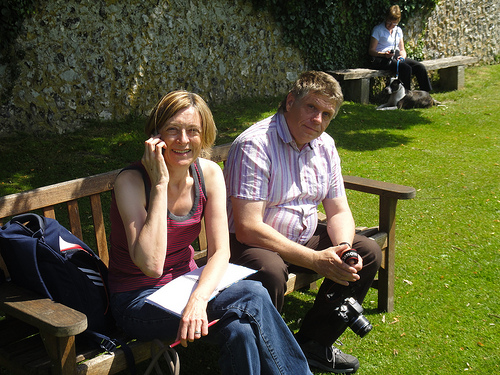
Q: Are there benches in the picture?
A: Yes, there is a bench.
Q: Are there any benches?
A: Yes, there is a bench.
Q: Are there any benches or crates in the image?
A: Yes, there is a bench.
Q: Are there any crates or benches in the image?
A: Yes, there is a bench.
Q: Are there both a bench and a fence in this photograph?
A: No, there is a bench but no fences.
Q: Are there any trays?
A: No, there are no trays.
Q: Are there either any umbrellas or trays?
A: No, there are no trays or umbrellas.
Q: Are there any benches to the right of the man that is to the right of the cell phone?
A: Yes, there is a bench to the right of the man.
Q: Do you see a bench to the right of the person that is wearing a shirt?
A: Yes, there is a bench to the right of the man.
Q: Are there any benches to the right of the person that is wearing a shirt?
A: Yes, there is a bench to the right of the man.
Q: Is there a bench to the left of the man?
A: No, the bench is to the right of the man.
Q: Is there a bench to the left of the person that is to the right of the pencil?
A: No, the bench is to the right of the man.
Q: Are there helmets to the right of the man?
A: No, there is a bench to the right of the man.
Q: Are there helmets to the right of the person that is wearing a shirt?
A: No, there is a bench to the right of the man.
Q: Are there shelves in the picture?
A: No, there are no shelves.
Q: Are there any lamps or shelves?
A: No, there are no shelves or lamps.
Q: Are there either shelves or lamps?
A: No, there are no shelves or lamps.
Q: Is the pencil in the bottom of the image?
A: Yes, the pencil is in the bottom of the image.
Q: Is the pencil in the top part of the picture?
A: No, the pencil is in the bottom of the image.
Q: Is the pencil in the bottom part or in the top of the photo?
A: The pencil is in the bottom of the image.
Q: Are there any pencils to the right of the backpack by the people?
A: Yes, there is a pencil to the right of the backpack.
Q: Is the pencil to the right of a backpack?
A: Yes, the pencil is to the right of a backpack.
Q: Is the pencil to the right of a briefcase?
A: No, the pencil is to the right of a backpack.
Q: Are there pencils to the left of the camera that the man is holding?
A: Yes, there is a pencil to the left of the camera.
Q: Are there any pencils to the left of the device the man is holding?
A: Yes, there is a pencil to the left of the camera.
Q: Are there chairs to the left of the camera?
A: No, there is a pencil to the left of the camera.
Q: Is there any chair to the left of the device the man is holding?
A: No, there is a pencil to the left of the camera.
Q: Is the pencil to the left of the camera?
A: Yes, the pencil is to the left of the camera.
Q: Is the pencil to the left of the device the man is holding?
A: Yes, the pencil is to the left of the camera.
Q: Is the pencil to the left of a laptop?
A: No, the pencil is to the left of the camera.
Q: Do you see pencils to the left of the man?
A: Yes, there is a pencil to the left of the man.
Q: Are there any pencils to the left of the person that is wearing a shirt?
A: Yes, there is a pencil to the left of the man.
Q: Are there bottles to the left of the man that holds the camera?
A: No, there is a pencil to the left of the man.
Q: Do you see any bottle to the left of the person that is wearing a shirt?
A: No, there is a pencil to the left of the man.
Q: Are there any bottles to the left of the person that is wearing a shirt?
A: No, there is a pencil to the left of the man.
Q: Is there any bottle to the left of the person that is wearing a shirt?
A: No, there is a pencil to the left of the man.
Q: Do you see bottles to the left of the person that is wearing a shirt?
A: No, there is a pencil to the left of the man.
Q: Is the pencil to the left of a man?
A: Yes, the pencil is to the left of a man.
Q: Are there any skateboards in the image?
A: No, there are no skateboards.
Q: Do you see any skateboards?
A: No, there are no skateboards.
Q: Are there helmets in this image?
A: No, there are no helmets.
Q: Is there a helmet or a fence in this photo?
A: No, there are no helmets or fences.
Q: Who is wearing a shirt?
A: The man is wearing a shirt.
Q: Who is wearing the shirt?
A: The man is wearing a shirt.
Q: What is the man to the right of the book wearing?
A: The man is wearing a shirt.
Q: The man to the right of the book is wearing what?
A: The man is wearing a shirt.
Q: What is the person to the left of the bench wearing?
A: The man is wearing a shirt.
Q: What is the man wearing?
A: The man is wearing a shirt.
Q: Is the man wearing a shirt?
A: Yes, the man is wearing a shirt.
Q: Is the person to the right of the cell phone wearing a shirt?
A: Yes, the man is wearing a shirt.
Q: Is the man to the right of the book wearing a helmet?
A: No, the man is wearing a shirt.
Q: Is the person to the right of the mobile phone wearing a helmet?
A: No, the man is wearing a shirt.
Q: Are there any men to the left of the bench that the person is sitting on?
A: Yes, there is a man to the left of the bench.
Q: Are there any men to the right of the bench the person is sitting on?
A: No, the man is to the left of the bench.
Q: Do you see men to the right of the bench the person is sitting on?
A: No, the man is to the left of the bench.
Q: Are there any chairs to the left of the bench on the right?
A: No, there is a man to the left of the bench.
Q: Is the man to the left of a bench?
A: Yes, the man is to the left of a bench.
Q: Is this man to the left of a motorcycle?
A: No, the man is to the left of a bench.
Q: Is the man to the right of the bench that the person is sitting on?
A: No, the man is to the left of the bench.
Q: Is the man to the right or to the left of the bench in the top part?
A: The man is to the left of the bench.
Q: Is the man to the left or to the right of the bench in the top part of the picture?
A: The man is to the left of the bench.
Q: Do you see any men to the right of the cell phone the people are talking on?
A: Yes, there is a man to the right of the mobile phone.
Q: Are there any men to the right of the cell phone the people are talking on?
A: Yes, there is a man to the right of the mobile phone.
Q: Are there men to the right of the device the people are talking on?
A: Yes, there is a man to the right of the mobile phone.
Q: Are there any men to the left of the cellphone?
A: No, the man is to the right of the cellphone.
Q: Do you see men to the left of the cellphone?
A: No, the man is to the right of the cellphone.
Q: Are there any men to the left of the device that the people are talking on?
A: No, the man is to the right of the cellphone.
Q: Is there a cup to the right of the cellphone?
A: No, there is a man to the right of the cellphone.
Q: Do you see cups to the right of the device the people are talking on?
A: No, there is a man to the right of the cellphone.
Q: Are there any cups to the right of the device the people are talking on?
A: No, there is a man to the right of the cellphone.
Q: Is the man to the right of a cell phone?
A: Yes, the man is to the right of a cell phone.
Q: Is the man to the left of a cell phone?
A: No, the man is to the right of a cell phone.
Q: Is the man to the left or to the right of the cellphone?
A: The man is to the right of the cellphone.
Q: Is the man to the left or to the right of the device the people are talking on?
A: The man is to the right of the cellphone.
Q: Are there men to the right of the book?
A: Yes, there is a man to the right of the book.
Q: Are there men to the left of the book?
A: No, the man is to the right of the book.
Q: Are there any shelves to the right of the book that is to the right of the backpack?
A: No, there is a man to the right of the book.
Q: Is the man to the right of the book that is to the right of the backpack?
A: Yes, the man is to the right of the book.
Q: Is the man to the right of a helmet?
A: No, the man is to the right of the book.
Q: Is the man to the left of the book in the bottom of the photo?
A: No, the man is to the right of the book.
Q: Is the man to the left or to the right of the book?
A: The man is to the right of the book.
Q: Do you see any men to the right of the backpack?
A: Yes, there is a man to the right of the backpack.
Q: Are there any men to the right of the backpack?
A: Yes, there is a man to the right of the backpack.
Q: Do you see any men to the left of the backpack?
A: No, the man is to the right of the backpack.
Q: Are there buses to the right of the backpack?
A: No, there is a man to the right of the backpack.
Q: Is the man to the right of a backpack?
A: Yes, the man is to the right of a backpack.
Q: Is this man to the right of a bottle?
A: No, the man is to the right of a backpack.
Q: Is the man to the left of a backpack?
A: No, the man is to the right of a backpack.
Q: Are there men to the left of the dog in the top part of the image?
A: Yes, there is a man to the left of the dog.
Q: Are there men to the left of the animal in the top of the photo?
A: Yes, there is a man to the left of the dog.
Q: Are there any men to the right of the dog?
A: No, the man is to the left of the dog.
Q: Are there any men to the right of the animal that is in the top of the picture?
A: No, the man is to the left of the dog.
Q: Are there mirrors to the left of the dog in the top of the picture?
A: No, there is a man to the left of the dog.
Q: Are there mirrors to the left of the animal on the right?
A: No, there is a man to the left of the dog.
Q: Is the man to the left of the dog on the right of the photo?
A: Yes, the man is to the left of the dog.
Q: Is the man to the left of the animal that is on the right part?
A: Yes, the man is to the left of the dog.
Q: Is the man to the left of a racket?
A: No, the man is to the left of the dog.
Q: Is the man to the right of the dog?
A: No, the man is to the left of the dog.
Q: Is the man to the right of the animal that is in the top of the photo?
A: No, the man is to the left of the dog.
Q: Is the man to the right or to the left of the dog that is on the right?
A: The man is to the left of the dog.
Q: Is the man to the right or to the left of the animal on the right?
A: The man is to the left of the dog.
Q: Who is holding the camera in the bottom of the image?
A: The man is holding the camera.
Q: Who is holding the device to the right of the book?
A: The man is holding the camera.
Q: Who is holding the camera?
A: The man is holding the camera.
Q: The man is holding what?
A: The man is holding the camera.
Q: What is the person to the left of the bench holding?
A: The man is holding the camera.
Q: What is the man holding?
A: The man is holding the camera.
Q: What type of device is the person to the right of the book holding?
A: The man is holding the camera.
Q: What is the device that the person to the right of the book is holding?
A: The device is a camera.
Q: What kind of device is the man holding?
A: The man is holding the camera.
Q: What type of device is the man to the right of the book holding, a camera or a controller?
A: The man is holding a camera.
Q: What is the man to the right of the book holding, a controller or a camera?
A: The man is holding a camera.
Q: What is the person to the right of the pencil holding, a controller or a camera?
A: The man is holding a camera.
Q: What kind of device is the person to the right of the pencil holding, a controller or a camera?
A: The man is holding a camera.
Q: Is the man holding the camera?
A: Yes, the man is holding the camera.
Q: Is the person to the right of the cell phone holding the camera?
A: Yes, the man is holding the camera.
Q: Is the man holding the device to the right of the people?
A: Yes, the man is holding the camera.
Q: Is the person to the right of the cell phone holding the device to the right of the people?
A: Yes, the man is holding the camera.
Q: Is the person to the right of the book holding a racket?
A: No, the man is holding the camera.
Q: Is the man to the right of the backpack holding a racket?
A: No, the man is holding the camera.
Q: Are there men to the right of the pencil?
A: Yes, there is a man to the right of the pencil.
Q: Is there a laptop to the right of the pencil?
A: No, there is a man to the right of the pencil.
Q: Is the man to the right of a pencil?
A: Yes, the man is to the right of a pencil.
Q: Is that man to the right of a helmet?
A: No, the man is to the right of a pencil.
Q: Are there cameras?
A: Yes, there is a camera.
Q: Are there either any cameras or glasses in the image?
A: Yes, there is a camera.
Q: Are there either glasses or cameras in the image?
A: Yes, there is a camera.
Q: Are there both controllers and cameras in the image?
A: No, there is a camera but no controllers.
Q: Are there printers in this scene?
A: No, there are no printers.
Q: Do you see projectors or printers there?
A: No, there are no printers or projectors.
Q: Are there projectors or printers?
A: No, there are no printers or projectors.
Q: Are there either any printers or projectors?
A: No, there are no printers or projectors.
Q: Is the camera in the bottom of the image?
A: Yes, the camera is in the bottom of the image.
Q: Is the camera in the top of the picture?
A: No, the camera is in the bottom of the image.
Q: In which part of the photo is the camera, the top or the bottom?
A: The camera is in the bottom of the image.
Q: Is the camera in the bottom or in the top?
A: The camera is in the bottom of the image.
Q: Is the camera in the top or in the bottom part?
A: The camera is in the bottom of the image.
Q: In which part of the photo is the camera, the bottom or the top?
A: The camera is in the bottom of the image.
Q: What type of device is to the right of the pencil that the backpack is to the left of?
A: The device is a camera.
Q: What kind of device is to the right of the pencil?
A: The device is a camera.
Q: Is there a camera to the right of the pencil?
A: Yes, there is a camera to the right of the pencil.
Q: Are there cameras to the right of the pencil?
A: Yes, there is a camera to the right of the pencil.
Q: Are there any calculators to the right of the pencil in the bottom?
A: No, there is a camera to the right of the pencil.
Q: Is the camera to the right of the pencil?
A: Yes, the camera is to the right of the pencil.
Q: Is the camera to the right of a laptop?
A: No, the camera is to the right of the pencil.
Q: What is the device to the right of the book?
A: The device is a camera.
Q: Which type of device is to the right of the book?
A: The device is a camera.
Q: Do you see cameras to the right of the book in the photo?
A: Yes, there is a camera to the right of the book.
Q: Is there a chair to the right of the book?
A: No, there is a camera to the right of the book.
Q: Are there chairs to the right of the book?
A: No, there is a camera to the right of the book.